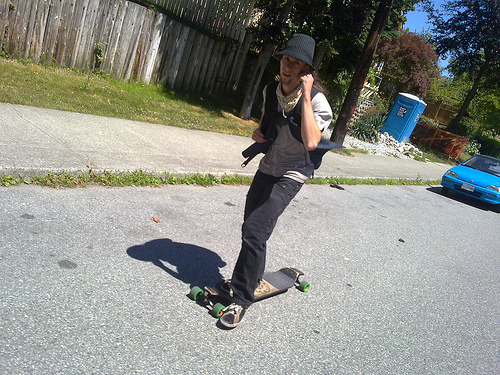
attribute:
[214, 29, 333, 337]
man — riding, looking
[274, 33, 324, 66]
fedora — black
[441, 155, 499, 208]
car — blue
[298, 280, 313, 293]
wheel — green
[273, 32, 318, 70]
hat — black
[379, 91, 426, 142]
port a potty — blue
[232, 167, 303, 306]
jeans — black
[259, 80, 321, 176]
vest — black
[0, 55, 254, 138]
grass — green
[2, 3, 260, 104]
fence — wooden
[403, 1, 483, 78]
sky — blue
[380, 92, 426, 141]
trash bag — blue, big